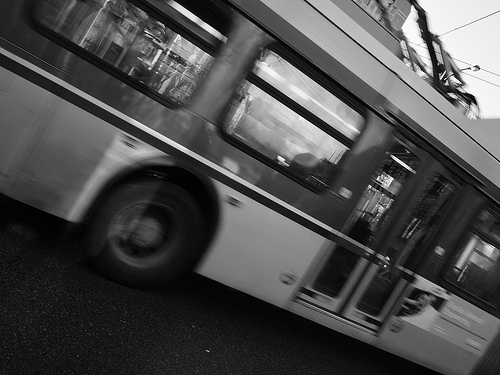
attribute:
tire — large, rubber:
[89, 165, 216, 292]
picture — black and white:
[14, 19, 487, 369]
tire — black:
[74, 156, 219, 295]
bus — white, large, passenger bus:
[1, 1, 498, 373]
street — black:
[0, 270, 323, 372]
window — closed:
[212, 28, 382, 213]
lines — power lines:
[431, 5, 494, 66]